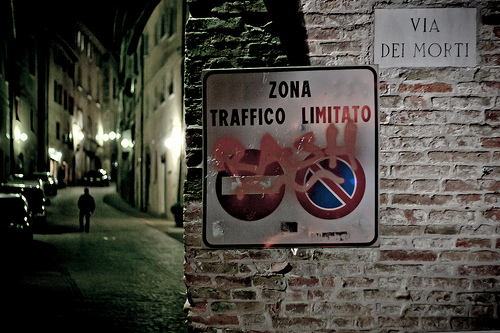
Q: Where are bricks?
A: On a wall.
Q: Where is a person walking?
A: On the road.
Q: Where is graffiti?
A: On sign on the left.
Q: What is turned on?
A: Lights.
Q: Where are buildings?
A: On buildings.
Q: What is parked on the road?
A: Cars.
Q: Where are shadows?
A: On the ground.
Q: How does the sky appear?
A: Dark.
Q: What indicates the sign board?
A: Street name.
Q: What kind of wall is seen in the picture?
A: A brick wall.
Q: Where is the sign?
A: On a building.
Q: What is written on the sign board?
A: Zona Traffico Limitato.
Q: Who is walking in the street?
A: A man.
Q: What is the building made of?
A: Bricks.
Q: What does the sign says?
A: Do not smoke.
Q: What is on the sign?
A: Graffiti.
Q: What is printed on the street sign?
A: Zona Traffico Limitato.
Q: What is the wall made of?
A: Bricks.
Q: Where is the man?
A: On street.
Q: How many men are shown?
A: One.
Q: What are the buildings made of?
A: Stone.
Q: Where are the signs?
A: On wall.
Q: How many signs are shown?
A: Two.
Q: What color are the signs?
A: White.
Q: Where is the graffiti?
A: Bottom sign.